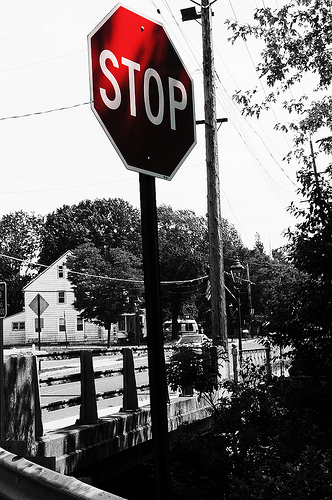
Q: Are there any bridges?
A: Yes, there is a bridge.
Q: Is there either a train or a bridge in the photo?
A: Yes, there is a bridge.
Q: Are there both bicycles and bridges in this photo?
A: No, there is a bridge but no bikes.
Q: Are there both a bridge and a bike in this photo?
A: No, there is a bridge but no bikes.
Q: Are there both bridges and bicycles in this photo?
A: No, there is a bridge but no bikes.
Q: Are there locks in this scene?
A: No, there are no locks.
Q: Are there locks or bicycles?
A: No, there are no locks or bicycles.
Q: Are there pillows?
A: No, there are no pillows.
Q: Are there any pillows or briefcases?
A: No, there are no pillows or briefcases.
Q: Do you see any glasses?
A: No, there are no glasses.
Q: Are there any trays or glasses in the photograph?
A: No, there are no glasses or trays.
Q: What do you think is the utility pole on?
A: The utility pole is on the bridge.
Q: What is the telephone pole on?
A: The utility pole is on the bridge.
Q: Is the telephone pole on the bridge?
A: Yes, the telephone pole is on the bridge.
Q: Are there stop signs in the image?
A: Yes, there is a stop sign.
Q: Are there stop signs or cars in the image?
A: Yes, there is a stop sign.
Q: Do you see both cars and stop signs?
A: Yes, there are both a stop sign and a car.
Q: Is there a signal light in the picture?
A: No, there are no traffic lights.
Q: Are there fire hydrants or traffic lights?
A: No, there are no traffic lights or fire hydrants.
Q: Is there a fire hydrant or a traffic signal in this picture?
A: No, there are no traffic lights or fire hydrants.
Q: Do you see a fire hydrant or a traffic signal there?
A: No, there are no traffic lights or fire hydrants.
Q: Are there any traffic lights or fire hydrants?
A: No, there are no traffic lights or fire hydrants.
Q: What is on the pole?
A: The stop sign is on the pole.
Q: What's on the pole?
A: The stop sign is on the pole.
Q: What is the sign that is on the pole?
A: The sign is a stop sign.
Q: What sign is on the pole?
A: The sign is a stop sign.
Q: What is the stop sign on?
A: The stop sign is on the pole.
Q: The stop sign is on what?
A: The stop sign is on the pole.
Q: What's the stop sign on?
A: The stop sign is on the pole.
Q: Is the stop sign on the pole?
A: Yes, the stop sign is on the pole.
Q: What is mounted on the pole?
A: The stop sign is mounted on the pole.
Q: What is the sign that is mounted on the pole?
A: The sign is a stop sign.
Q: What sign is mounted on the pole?
A: The sign is a stop sign.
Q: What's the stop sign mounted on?
A: The stop sign is mounted on the pole.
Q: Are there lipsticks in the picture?
A: No, there are no lipsticks.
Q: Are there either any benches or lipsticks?
A: No, there are no lipsticks or benches.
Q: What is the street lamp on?
A: The street lamp is on the bridge.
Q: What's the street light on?
A: The street lamp is on the bridge.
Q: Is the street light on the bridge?
A: Yes, the street light is on the bridge.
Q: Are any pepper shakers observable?
A: No, there are no pepper shakers.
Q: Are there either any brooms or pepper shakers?
A: No, there are no pepper shakers or brooms.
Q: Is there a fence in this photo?
A: Yes, there is a fence.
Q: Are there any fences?
A: Yes, there is a fence.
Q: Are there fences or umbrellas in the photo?
A: Yes, there is a fence.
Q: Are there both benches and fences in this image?
A: No, there is a fence but no benches.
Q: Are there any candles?
A: No, there are no candles.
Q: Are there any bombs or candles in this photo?
A: No, there are no candles or bombs.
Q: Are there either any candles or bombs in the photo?
A: No, there are no candles or bombs.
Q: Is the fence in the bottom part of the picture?
A: Yes, the fence is in the bottom of the image.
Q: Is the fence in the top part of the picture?
A: No, the fence is in the bottom of the image.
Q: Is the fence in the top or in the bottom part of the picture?
A: The fence is in the bottom of the image.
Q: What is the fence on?
A: The fence is on the bridge.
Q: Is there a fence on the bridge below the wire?
A: Yes, there is a fence on the bridge.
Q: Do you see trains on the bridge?
A: No, there is a fence on the bridge.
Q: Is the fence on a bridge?
A: Yes, the fence is on a bridge.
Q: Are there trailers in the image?
A: No, there are no trailers.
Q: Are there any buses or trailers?
A: No, there are no trailers or buses.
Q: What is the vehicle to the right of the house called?
A: The vehicle is a van.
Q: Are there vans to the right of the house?
A: Yes, there is a van to the right of the house.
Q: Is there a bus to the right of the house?
A: No, there is a van to the right of the house.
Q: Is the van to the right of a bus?
A: No, the van is to the right of the house.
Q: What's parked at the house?
A: The van is parked at the house.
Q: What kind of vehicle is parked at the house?
A: The vehicle is a van.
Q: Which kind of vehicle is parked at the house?
A: The vehicle is a van.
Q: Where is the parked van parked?
A: The van is parked at the house.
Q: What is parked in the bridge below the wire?
A: The van is parked in the bridge.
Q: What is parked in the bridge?
A: The van is parked in the bridge.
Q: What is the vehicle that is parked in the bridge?
A: The vehicle is a van.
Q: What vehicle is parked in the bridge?
A: The vehicle is a van.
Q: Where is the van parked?
A: The van is parked in the bridge.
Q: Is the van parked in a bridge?
A: Yes, the van is parked in a bridge.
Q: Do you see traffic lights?
A: No, there are no traffic lights.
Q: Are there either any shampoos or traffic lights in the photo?
A: No, there are no traffic lights or shampoos.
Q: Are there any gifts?
A: No, there are no gifts.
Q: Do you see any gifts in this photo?
A: No, there are no gifts.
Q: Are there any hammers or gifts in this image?
A: No, there are no gifts or hammers.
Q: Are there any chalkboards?
A: No, there are no chalkboards.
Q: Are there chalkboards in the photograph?
A: No, there are no chalkboards.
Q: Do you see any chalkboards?
A: No, there are no chalkboards.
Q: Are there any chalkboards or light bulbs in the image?
A: No, there are no chalkboards or light bulbs.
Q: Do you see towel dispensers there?
A: No, there are no towel dispensers.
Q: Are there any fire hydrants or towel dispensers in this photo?
A: No, there are no towel dispensers or fire hydrants.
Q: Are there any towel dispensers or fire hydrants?
A: No, there are no towel dispensers or fire hydrants.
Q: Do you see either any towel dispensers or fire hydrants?
A: No, there are no towel dispensers or fire hydrants.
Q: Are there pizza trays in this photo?
A: No, there are no pizza trays.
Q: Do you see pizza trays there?
A: No, there are no pizza trays.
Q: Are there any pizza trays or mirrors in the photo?
A: No, there are no pizza trays or mirrors.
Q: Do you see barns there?
A: No, there are no barns.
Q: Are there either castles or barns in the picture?
A: No, there are no barns or castles.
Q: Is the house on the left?
A: Yes, the house is on the left of the image.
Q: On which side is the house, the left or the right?
A: The house is on the left of the image.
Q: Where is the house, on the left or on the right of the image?
A: The house is on the left of the image.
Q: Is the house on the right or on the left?
A: The house is on the left of the image.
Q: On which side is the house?
A: The house is on the left of the image.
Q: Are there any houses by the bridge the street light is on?
A: Yes, there is a house by the bridge.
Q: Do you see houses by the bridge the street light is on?
A: Yes, there is a house by the bridge.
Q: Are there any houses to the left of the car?
A: Yes, there is a house to the left of the car.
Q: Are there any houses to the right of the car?
A: No, the house is to the left of the car.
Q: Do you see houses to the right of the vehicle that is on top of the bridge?
A: No, the house is to the left of the car.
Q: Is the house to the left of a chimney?
A: No, the house is to the left of a car.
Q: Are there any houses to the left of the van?
A: Yes, there is a house to the left of the van.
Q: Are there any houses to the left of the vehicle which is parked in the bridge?
A: Yes, there is a house to the left of the van.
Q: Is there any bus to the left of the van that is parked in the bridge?
A: No, there is a house to the left of the van.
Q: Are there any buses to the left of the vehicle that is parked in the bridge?
A: No, there is a house to the left of the van.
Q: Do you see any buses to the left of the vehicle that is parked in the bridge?
A: No, there is a house to the left of the van.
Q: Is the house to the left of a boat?
A: No, the house is to the left of the van.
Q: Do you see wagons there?
A: No, there are no wagons.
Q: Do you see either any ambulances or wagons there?
A: No, there are no wagons or ambulances.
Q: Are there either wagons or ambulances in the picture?
A: No, there are no wagons or ambulances.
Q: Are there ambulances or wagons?
A: No, there are no wagons or ambulances.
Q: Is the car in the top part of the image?
A: No, the car is in the bottom of the image.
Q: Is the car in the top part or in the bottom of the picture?
A: The car is in the bottom of the image.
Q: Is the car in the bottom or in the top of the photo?
A: The car is in the bottom of the image.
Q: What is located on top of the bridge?
A: The car is on top of the bridge.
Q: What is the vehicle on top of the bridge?
A: The vehicle is a car.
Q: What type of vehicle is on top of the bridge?
A: The vehicle is a car.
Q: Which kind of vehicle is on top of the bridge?
A: The vehicle is a car.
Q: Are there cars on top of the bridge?
A: Yes, there is a car on top of the bridge.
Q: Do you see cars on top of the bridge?
A: Yes, there is a car on top of the bridge.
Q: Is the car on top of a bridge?
A: Yes, the car is on top of a bridge.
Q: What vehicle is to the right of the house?
A: The vehicle is a car.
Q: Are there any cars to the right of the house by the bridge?
A: Yes, there is a car to the right of the house.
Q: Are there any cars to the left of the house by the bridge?
A: No, the car is to the right of the house.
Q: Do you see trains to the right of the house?
A: No, there is a car to the right of the house.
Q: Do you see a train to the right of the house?
A: No, there is a car to the right of the house.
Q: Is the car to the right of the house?
A: Yes, the car is to the right of the house.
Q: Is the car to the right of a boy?
A: No, the car is to the right of the house.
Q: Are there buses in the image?
A: No, there are no buses.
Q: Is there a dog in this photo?
A: No, there are no dogs.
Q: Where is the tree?
A: The tree is in the yard.